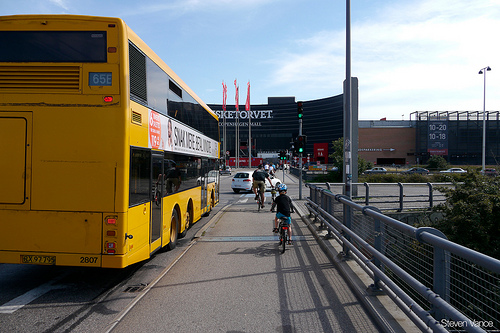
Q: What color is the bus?
A: Yellow.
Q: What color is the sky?
A: Blue.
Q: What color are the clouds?
A: White.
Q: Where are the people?
A: On the sidewalk.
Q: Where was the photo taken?
A: Outdoors somewhere.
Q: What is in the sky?
A: Clouds.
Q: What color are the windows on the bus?
A: The bus has black windows.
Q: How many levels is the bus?
A: The bus is two levels.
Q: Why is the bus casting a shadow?
A: Because of the position of the sun.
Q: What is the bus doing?
A: The bus is crossing a bridge.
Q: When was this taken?
A: Daytime.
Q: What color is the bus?
A: Yellow.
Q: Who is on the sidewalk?
A: Bike riders.